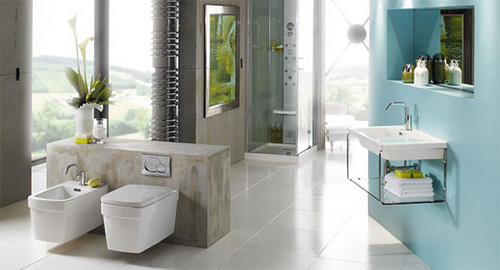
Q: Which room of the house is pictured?
A: It is a bathroom.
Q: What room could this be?
A: It is a bathroom.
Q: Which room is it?
A: It is a bathroom.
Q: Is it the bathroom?
A: Yes, it is the bathroom.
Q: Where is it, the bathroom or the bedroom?
A: It is the bathroom.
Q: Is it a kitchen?
A: No, it is a bathroom.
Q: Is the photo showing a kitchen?
A: No, the picture is showing a bathroom.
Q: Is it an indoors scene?
A: Yes, it is indoors.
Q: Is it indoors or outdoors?
A: It is indoors.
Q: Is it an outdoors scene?
A: No, it is indoors.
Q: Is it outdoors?
A: No, it is indoors.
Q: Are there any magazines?
A: No, there are no magazines.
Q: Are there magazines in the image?
A: No, there are no magazines.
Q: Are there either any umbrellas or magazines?
A: No, there are no magazines or umbrellas.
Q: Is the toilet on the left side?
A: Yes, the toilet is on the left of the image.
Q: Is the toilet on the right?
A: No, the toilet is on the left of the image.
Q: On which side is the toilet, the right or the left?
A: The toilet is on the left of the image.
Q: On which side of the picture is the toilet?
A: The toilet is on the left of the image.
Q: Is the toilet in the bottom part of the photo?
A: Yes, the toilet is in the bottom of the image.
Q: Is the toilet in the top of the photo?
A: No, the toilet is in the bottom of the image.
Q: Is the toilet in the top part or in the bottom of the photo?
A: The toilet is in the bottom of the image.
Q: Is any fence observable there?
A: No, there are no fences.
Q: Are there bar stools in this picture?
A: No, there are no bar stools.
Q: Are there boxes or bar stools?
A: No, there are no bar stools or boxes.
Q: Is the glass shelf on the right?
A: Yes, the shelf is on the right of the image.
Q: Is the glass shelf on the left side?
A: No, the shelf is on the right of the image.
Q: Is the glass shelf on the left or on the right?
A: The shelf is on the right of the image.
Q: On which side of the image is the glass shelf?
A: The shelf is on the right of the image.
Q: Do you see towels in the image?
A: Yes, there is a towel.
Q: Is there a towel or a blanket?
A: Yes, there is a towel.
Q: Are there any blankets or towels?
A: Yes, there is a towel.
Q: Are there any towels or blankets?
A: Yes, there is a towel.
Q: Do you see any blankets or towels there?
A: Yes, there is a towel.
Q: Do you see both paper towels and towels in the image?
A: No, there is a towel but no paper towels.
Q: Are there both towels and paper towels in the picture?
A: No, there is a towel but no paper towels.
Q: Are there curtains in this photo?
A: No, there are no curtains.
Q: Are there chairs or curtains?
A: No, there are no curtains or chairs.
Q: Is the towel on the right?
A: Yes, the towel is on the right of the image.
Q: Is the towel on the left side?
A: No, the towel is on the right of the image.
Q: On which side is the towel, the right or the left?
A: The towel is on the right of the image.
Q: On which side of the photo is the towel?
A: The towel is on the right of the image.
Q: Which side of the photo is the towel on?
A: The towel is on the right of the image.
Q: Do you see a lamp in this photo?
A: No, there are no lamps.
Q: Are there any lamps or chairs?
A: No, there are no lamps or chairs.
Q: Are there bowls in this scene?
A: No, there are no bowls.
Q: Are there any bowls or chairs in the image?
A: No, there are no bowls or chairs.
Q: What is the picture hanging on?
A: The picture is hanging on the wall.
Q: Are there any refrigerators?
A: No, there are no refrigerators.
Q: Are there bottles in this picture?
A: Yes, there is a bottle.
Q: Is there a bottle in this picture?
A: Yes, there is a bottle.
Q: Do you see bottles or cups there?
A: Yes, there is a bottle.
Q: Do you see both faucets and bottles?
A: Yes, there are both a bottle and a faucet.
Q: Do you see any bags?
A: No, there are no bags.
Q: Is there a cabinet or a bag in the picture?
A: No, there are no bags or cabinets.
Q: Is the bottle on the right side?
A: Yes, the bottle is on the right of the image.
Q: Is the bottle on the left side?
A: No, the bottle is on the right of the image.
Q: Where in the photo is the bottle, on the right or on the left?
A: The bottle is on the right of the image.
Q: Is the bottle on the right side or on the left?
A: The bottle is on the right of the image.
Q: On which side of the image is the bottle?
A: The bottle is on the right of the image.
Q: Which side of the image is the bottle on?
A: The bottle is on the right of the image.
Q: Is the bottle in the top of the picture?
A: Yes, the bottle is in the top of the image.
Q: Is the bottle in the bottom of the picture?
A: No, the bottle is in the top of the image.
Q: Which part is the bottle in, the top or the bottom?
A: The bottle is in the top of the image.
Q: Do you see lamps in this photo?
A: No, there are no lamps.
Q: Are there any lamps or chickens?
A: No, there are no lamps or chickens.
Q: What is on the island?
A: The plant is on the island.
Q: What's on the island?
A: The plant is on the island.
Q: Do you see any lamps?
A: No, there are no lamps.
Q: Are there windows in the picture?
A: Yes, there is a window.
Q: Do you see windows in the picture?
A: Yes, there is a window.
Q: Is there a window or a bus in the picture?
A: Yes, there is a window.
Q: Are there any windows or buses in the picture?
A: Yes, there is a window.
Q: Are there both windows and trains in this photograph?
A: No, there is a window but no trains.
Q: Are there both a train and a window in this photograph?
A: No, there is a window but no trains.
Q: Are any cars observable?
A: No, there are no cars.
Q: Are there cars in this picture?
A: No, there are no cars.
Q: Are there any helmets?
A: No, there are no helmets.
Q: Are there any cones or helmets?
A: No, there are no helmets or cones.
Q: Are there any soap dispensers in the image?
A: No, there are no soap dispensers.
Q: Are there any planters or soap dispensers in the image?
A: No, there are no soap dispensers or planters.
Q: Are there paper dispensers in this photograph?
A: No, there are no paper dispensers.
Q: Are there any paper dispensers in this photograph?
A: No, there are no paper dispensers.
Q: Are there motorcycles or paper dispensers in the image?
A: No, there are no paper dispensers or motorcycles.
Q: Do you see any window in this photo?
A: Yes, there is a window.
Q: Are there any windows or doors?
A: Yes, there is a window.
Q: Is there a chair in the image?
A: No, there are no chairs.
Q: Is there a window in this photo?
A: Yes, there is a window.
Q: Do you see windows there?
A: Yes, there is a window.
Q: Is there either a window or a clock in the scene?
A: Yes, there is a window.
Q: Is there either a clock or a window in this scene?
A: Yes, there is a window.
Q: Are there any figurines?
A: No, there are no figurines.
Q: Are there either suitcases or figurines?
A: No, there are no figurines or suitcases.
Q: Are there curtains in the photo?
A: No, there are no curtains.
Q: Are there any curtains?
A: No, there are no curtains.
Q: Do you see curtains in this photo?
A: No, there are no curtains.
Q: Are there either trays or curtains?
A: No, there are no curtains or trays.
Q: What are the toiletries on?
A: The toiletries are on the shelf.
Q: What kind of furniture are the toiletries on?
A: The toiletries are on the shelf.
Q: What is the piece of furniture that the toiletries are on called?
A: The piece of furniture is a shelf.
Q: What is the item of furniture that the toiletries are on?
A: The piece of furniture is a shelf.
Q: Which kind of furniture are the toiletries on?
A: The toiletries are on the shelf.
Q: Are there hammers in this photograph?
A: No, there are no hammers.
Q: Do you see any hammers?
A: No, there are no hammers.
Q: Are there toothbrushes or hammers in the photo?
A: No, there are no hammers or toothbrushes.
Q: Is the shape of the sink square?
A: Yes, the sink is square.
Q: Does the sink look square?
A: Yes, the sink is square.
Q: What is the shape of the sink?
A: The sink is square.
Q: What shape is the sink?
A: The sink is square.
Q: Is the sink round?
A: No, the sink is square.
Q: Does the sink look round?
A: No, the sink is square.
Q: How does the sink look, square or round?
A: The sink is square.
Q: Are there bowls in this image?
A: No, there are no bowls.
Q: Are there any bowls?
A: No, there are no bowls.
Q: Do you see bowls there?
A: No, there are no bowls.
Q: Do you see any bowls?
A: No, there are no bowls.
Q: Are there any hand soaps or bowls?
A: No, there are no bowls or hand soaps.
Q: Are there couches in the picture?
A: No, there are no couches.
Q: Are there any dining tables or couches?
A: No, there are no couches or dining tables.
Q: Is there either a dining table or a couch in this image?
A: No, there are no couches or dining tables.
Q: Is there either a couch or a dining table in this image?
A: No, there are no couches or dining tables.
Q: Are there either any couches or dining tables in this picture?
A: No, there are no couches or dining tables.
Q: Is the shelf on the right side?
A: Yes, the shelf is on the right of the image.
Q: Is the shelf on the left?
A: No, the shelf is on the right of the image.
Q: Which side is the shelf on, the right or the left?
A: The shelf is on the right of the image.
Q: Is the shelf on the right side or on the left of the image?
A: The shelf is on the right of the image.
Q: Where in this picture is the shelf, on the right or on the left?
A: The shelf is on the right of the image.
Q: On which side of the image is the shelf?
A: The shelf is on the right of the image.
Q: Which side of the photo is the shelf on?
A: The shelf is on the right of the image.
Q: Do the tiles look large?
A: Yes, the tiles are large.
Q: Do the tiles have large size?
A: Yes, the tiles are large.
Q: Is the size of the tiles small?
A: No, the tiles are large.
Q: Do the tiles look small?
A: No, the tiles are large.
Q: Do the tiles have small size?
A: No, the tiles are large.